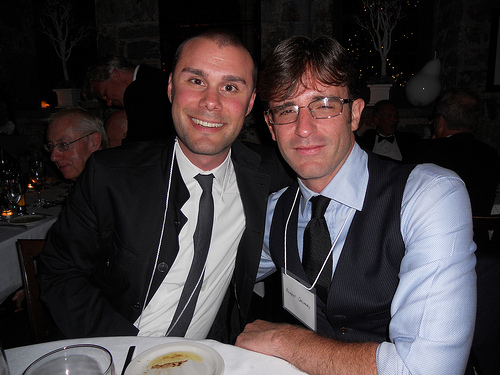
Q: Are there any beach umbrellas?
A: No, there are no beach umbrellas.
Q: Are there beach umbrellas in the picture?
A: No, there are no beach umbrellas.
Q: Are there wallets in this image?
A: No, there are no wallets.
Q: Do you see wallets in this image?
A: No, there are no wallets.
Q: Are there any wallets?
A: No, there are no wallets.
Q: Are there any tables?
A: Yes, there is a table.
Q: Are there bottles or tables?
A: Yes, there is a table.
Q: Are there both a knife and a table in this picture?
A: No, there is a table but no knives.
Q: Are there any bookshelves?
A: No, there are no bookshelves.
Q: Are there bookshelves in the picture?
A: No, there are no bookshelves.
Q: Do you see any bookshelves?
A: No, there are no bookshelves.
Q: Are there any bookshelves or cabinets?
A: No, there are no bookshelves or cabinets.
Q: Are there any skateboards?
A: No, there are no skateboards.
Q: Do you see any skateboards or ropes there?
A: No, there are no skateboards or ropes.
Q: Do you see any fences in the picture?
A: No, there are no fences.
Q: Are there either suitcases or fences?
A: No, there are no fences or suitcases.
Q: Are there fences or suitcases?
A: No, there are no fences or suitcases.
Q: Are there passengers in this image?
A: No, there are no passengers.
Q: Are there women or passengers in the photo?
A: No, there are no passengers or women.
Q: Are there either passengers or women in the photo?
A: No, there are no passengers or women.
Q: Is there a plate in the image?
A: Yes, there is a plate.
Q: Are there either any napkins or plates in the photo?
A: Yes, there is a plate.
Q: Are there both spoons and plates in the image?
A: No, there is a plate but no spoons.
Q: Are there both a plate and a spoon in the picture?
A: No, there is a plate but no spoons.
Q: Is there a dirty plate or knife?
A: Yes, there is a dirty plate.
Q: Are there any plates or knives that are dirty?
A: Yes, the plate is dirty.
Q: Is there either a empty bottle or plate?
A: Yes, there is an empty plate.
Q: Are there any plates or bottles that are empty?
A: Yes, the plate is empty.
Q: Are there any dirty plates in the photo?
A: Yes, there is a dirty plate.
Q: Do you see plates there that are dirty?
A: Yes, there is a plate that is dirty.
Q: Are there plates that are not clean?
A: Yes, there is a dirty plate.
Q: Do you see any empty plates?
A: Yes, there is an empty plate.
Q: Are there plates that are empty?
A: Yes, there is a plate that is empty.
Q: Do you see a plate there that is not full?
A: Yes, there is a empty plate.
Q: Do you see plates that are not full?
A: Yes, there is a empty plate.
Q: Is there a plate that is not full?
A: Yes, there is a empty plate.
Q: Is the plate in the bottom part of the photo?
A: Yes, the plate is in the bottom of the image.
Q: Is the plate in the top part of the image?
A: No, the plate is in the bottom of the image.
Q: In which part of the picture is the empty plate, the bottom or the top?
A: The plate is in the bottom of the image.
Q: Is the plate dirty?
A: Yes, the plate is dirty.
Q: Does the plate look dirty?
A: Yes, the plate is dirty.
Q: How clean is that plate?
A: The plate is dirty.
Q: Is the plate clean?
A: No, the plate is dirty.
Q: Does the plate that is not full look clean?
A: No, the plate is dirty.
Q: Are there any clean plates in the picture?
A: No, there is a plate but it is dirty.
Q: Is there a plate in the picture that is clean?
A: No, there is a plate but it is dirty.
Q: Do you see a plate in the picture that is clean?
A: No, there is a plate but it is dirty.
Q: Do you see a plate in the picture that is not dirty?
A: No, there is a plate but it is dirty.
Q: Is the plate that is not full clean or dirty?
A: The plate is dirty.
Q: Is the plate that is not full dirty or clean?
A: The plate is dirty.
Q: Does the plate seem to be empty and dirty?
A: Yes, the plate is empty and dirty.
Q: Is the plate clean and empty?
A: No, the plate is empty but dirty.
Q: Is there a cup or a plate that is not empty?
A: No, there is a plate but it is empty.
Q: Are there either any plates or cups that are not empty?
A: No, there is a plate but it is empty.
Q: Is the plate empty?
A: Yes, the plate is empty.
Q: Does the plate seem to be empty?
A: Yes, the plate is empty.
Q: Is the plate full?
A: No, the plate is empty.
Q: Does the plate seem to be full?
A: No, the plate is empty.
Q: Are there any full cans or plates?
A: No, there is a plate but it is empty.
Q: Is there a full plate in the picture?
A: No, there is a plate but it is empty.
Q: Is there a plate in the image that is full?
A: No, there is a plate but it is empty.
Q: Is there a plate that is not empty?
A: No, there is a plate but it is empty.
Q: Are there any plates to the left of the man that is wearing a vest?
A: Yes, there is a plate to the left of the man.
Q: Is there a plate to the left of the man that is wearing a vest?
A: Yes, there is a plate to the left of the man.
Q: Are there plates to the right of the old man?
A: No, the plate is to the left of the man.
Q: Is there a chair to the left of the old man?
A: No, there is a plate to the left of the man.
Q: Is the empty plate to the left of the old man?
A: Yes, the plate is to the left of the man.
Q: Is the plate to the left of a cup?
A: No, the plate is to the left of the man.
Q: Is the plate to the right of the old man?
A: No, the plate is to the left of the man.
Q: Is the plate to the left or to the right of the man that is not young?
A: The plate is to the left of the man.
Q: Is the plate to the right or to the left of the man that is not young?
A: The plate is to the left of the man.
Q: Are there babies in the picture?
A: No, there are no babies.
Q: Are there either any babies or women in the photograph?
A: No, there are no babies or women.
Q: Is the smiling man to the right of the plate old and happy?
A: Yes, the man is old and happy.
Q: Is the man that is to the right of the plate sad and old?
A: No, the man is old but happy.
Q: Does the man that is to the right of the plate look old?
A: Yes, the man is old.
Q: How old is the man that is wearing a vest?
A: The man is old.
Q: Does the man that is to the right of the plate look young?
A: No, the man is old.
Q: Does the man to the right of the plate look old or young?
A: The man is old.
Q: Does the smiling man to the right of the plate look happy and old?
A: Yes, the man is happy and old.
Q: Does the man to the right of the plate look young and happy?
A: No, the man is happy but old.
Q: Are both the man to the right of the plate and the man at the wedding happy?
A: Yes, both the man and the man are happy.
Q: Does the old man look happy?
A: Yes, the man is happy.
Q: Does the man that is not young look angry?
A: No, the man is happy.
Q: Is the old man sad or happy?
A: The man is happy.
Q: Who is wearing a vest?
A: The man is wearing a vest.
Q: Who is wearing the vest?
A: The man is wearing a vest.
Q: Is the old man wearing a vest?
A: Yes, the man is wearing a vest.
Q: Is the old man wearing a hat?
A: No, the man is wearing a vest.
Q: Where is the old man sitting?
A: The man is sitting at the table.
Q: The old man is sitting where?
A: The man is sitting at the table.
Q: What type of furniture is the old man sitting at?
A: The man is sitting at the table.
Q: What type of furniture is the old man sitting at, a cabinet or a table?
A: The man is sitting at a table.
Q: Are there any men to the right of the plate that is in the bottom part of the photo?
A: Yes, there is a man to the right of the plate.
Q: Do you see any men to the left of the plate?
A: No, the man is to the right of the plate.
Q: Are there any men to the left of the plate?
A: No, the man is to the right of the plate.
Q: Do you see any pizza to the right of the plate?
A: No, there is a man to the right of the plate.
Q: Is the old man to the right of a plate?
A: Yes, the man is to the right of a plate.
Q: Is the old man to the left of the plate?
A: No, the man is to the right of the plate.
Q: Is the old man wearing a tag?
A: Yes, the man is wearing a tag.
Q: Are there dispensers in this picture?
A: No, there are no dispensers.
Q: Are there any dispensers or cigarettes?
A: No, there are no dispensers or cigarettes.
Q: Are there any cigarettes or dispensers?
A: No, there are no dispensers or cigarettes.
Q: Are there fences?
A: No, there are no fences.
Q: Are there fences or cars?
A: No, there are no fences or cars.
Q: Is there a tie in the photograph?
A: Yes, there is a tie.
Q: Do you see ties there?
A: Yes, there is a tie.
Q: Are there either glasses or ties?
A: Yes, there is a tie.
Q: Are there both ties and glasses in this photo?
A: Yes, there are both a tie and glasses.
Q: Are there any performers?
A: No, there are no performers.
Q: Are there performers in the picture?
A: No, there are no performers.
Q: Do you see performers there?
A: No, there are no performers.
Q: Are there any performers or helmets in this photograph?
A: No, there are no performers or helmets.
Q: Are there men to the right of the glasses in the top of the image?
A: Yes, there is a man to the right of the glasses.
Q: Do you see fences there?
A: No, there are no fences.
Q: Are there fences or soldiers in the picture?
A: No, there are no fences or soldiers.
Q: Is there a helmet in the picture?
A: No, there are no helmets.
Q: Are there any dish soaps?
A: No, there are no dish soaps.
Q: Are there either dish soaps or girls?
A: No, there are no dish soaps or girls.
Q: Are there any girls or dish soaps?
A: No, there are no dish soaps or girls.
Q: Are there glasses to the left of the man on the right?
A: Yes, there are glasses to the left of the man.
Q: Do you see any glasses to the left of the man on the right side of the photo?
A: Yes, there are glasses to the left of the man.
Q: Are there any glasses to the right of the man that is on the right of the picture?
A: No, the glasses are to the left of the man.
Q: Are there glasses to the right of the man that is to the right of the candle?
A: Yes, there are glasses to the right of the man.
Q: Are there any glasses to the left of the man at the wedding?
A: No, the glasses are to the right of the man.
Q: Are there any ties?
A: Yes, there is a tie.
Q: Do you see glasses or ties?
A: Yes, there is a tie.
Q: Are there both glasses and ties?
A: Yes, there are both a tie and glasses.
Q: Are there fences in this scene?
A: No, there are no fences.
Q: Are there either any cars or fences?
A: No, there are no fences or cars.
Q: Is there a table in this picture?
A: Yes, there is a table.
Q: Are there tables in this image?
A: Yes, there is a table.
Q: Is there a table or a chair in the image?
A: Yes, there is a table.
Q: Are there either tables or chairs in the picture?
A: Yes, there is a table.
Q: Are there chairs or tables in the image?
A: Yes, there is a table.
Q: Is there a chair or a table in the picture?
A: Yes, there is a table.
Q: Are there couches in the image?
A: No, there are no couches.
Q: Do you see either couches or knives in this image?
A: No, there are no couches or knives.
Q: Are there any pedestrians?
A: No, there are no pedestrians.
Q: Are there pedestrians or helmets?
A: No, there are no pedestrians or helmets.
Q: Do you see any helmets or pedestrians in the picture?
A: No, there are no pedestrians or helmets.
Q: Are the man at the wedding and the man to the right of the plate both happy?
A: Yes, both the man and the man are happy.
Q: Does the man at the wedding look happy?
A: Yes, the man is happy.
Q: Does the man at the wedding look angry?
A: No, the man is happy.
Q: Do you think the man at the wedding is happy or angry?
A: The man is happy.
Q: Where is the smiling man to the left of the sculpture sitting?
A: The man is sitting at the table.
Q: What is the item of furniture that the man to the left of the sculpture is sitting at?
A: The piece of furniture is a table.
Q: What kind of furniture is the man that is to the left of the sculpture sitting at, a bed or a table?
A: The man is sitting at a table.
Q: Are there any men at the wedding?
A: Yes, there is a man at the wedding.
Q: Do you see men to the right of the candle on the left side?
A: Yes, there is a man to the right of the candle.